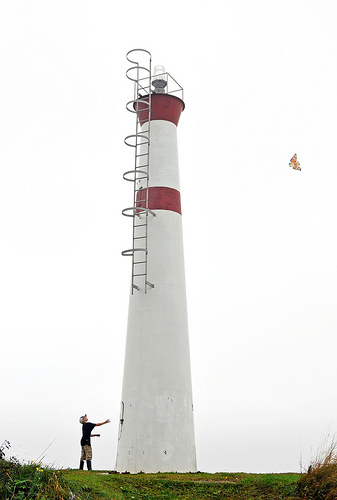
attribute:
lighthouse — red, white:
[94, 61, 214, 429]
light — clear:
[149, 77, 168, 93]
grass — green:
[46, 469, 301, 495]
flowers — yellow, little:
[33, 463, 242, 499]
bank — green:
[1, 463, 336, 498]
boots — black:
[78, 457, 92, 471]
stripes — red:
[120, 183, 191, 217]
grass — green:
[18, 471, 308, 496]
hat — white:
[78, 413, 86, 423]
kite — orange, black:
[289, 154, 301, 170]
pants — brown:
[73, 444, 94, 462]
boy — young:
[80, 415, 110, 470]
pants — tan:
[79, 444, 92, 460]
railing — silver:
[117, 44, 161, 299]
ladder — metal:
[120, 45, 153, 296]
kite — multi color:
[284, 149, 303, 173]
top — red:
[132, 92, 185, 126]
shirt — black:
[79, 421, 95, 444]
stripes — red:
[128, 93, 185, 216]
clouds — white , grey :
[22, 20, 334, 475]